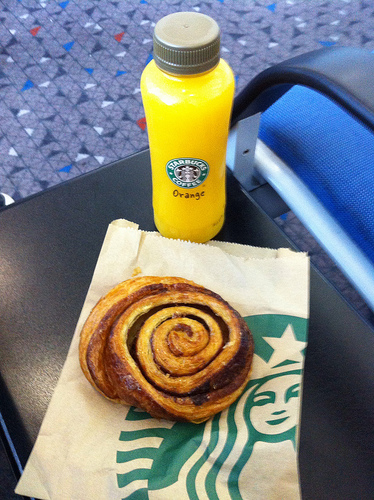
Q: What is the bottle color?
A: Yellow and grey.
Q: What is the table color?
A: Black.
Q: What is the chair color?
A: Blue and black.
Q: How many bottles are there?
A: One.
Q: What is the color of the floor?
A: Mainly grey.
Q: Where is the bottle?
A: In the table.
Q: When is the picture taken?
A: Daytime.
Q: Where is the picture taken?
A: Starbucks.